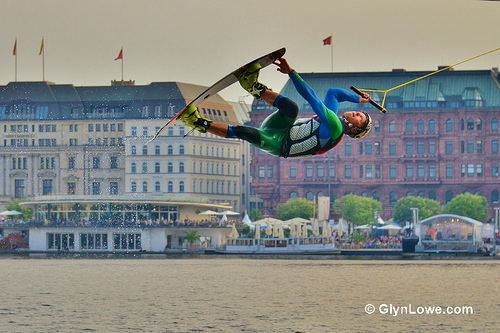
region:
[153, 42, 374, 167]
a man in the air with a ski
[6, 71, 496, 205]
two large buildings in the background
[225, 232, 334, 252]
a small boat in the water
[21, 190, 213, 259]
a building in the water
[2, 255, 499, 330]
the water below the man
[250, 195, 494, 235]
a line of trees in front of the building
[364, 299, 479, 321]
the trademark in the corner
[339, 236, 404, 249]
a group of people standing around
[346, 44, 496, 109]
the rope the man is holding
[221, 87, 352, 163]
the wetsuit the man is wearing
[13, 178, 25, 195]
a window on a building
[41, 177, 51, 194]
a window on a building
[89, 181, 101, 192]
a window on a building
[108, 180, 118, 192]
a window on a building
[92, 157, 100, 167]
a window on a building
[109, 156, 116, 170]
a window on a building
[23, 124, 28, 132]
a window on a building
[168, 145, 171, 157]
a window on a building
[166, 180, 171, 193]
a window on a building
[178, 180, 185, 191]
a window on a building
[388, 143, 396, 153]
a window on a building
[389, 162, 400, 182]
a window on a building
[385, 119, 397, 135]
a window on a building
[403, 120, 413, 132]
a window on a building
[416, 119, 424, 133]
a window on a building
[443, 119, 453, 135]
a window on a building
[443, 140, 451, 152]
a window on a building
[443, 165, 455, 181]
a window on a building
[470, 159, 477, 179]
a window on a building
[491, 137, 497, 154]
a window on a building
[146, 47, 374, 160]
person on water ski board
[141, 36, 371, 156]
person doing tricks on ski board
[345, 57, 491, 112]
water ski pull rope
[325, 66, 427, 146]
person holding on to rope handle with one hand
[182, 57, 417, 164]
person wearing multi colored wet suit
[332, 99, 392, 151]
person wearing safety helmet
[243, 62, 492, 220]
large brick building in background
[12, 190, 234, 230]
covered viewing area next to water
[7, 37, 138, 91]
flags on top of building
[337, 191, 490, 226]
trees along waterside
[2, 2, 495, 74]
sky appears dark grey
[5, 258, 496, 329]
body of water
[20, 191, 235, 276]
building with large balcony near water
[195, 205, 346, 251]
large patio umbrellas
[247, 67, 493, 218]
large red multistory building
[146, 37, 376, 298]
person water-skiing who is currently airborne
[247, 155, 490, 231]
green trees near building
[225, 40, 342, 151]
person's left hand touching board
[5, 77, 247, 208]
large cream colored building with dark roof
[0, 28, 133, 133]
flags on top of building